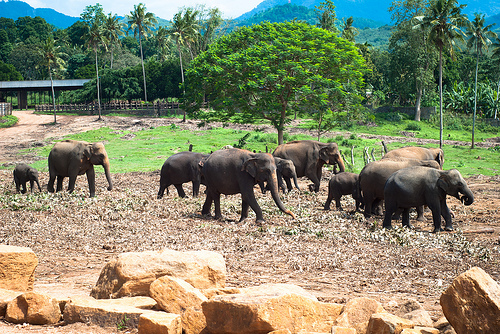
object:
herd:
[11, 139, 475, 233]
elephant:
[382, 166, 474, 233]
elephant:
[382, 147, 443, 171]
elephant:
[358, 158, 441, 220]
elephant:
[323, 170, 363, 213]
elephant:
[271, 140, 346, 194]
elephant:
[274, 156, 302, 195]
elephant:
[11, 162, 42, 195]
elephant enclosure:
[0, 244, 497, 334]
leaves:
[179, 21, 370, 144]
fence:
[29, 101, 208, 115]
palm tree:
[408, 0, 476, 126]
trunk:
[439, 61, 443, 148]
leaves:
[67, 2, 221, 54]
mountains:
[0, 0, 497, 21]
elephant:
[46, 138, 114, 198]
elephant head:
[437, 168, 474, 206]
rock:
[0, 243, 500, 334]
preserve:
[0, 102, 497, 334]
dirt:
[0, 115, 87, 135]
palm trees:
[67, 0, 132, 115]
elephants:
[0, 51, 500, 333]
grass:
[30, 192, 190, 242]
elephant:
[199, 145, 297, 224]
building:
[0, 79, 93, 112]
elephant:
[380, 146, 445, 212]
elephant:
[156, 151, 221, 200]